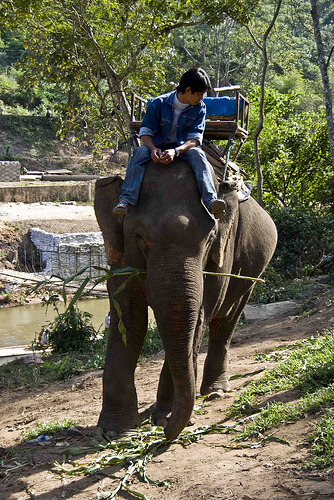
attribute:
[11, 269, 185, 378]
water — brown 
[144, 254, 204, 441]
trunk — wide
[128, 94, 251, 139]
seat — brown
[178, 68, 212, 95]
hair — black, brown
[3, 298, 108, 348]
water — brown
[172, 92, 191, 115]
turtleneck — white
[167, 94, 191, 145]
shirt — white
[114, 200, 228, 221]
shoes — blue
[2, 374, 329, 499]
ground — dry, brown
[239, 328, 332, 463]
grass — green